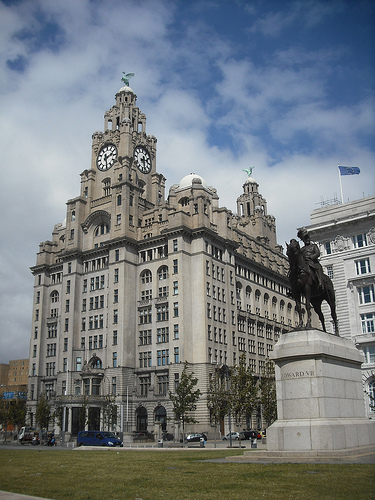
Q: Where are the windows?
A: On building.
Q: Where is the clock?
A: In tower.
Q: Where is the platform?
A: Under sculpture.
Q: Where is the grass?
A: On walkway.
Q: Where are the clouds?
A: Sky.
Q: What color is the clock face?
A: White.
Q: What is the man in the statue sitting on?
A: A horse.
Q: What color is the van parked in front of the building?
A: Blue.